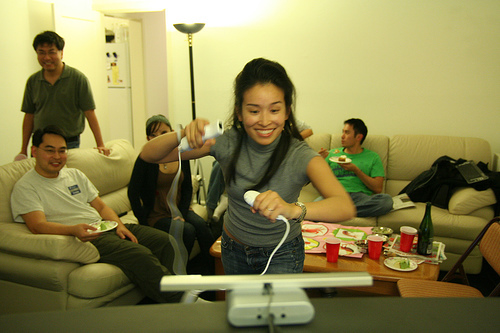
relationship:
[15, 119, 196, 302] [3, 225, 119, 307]
guy sitting on couch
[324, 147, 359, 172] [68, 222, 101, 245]
guy holding a plate in hand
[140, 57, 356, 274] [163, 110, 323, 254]
girl holding two controllers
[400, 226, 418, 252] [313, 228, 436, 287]
cup on table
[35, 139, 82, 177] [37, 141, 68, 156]
smiling man with glasses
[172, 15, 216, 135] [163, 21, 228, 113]
gold stand lamp by wall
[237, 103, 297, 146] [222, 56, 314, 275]
big smile on woman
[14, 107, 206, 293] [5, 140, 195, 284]
two people sitting on love seat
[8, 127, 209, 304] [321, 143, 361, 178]
guy wearing glasses holding plate of food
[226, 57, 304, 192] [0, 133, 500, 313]
dark long hair on couch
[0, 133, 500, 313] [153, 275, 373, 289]
couch playing wii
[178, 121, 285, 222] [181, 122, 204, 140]
two controllers in hand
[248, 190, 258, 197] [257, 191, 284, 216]
nunchuck in hand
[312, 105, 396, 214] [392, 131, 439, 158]
man eating on couch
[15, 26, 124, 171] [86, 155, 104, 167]
man standing behind couch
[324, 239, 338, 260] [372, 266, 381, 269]
cup on table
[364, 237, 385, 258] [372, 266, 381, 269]
cup on table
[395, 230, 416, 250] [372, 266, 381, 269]
cup on table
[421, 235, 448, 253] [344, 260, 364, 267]
corner of table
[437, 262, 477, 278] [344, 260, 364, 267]
chair by table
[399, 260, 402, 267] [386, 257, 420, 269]
food on utensil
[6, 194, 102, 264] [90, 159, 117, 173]
hand resting on couch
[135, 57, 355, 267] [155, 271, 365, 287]
girl playing wii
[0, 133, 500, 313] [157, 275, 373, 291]
couch playing video game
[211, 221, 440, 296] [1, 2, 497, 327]
coffee table in living room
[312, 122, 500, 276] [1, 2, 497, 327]
couch in living room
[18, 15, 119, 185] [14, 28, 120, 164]
man behind behind the couch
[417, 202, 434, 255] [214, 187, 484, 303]
bottle sitting on table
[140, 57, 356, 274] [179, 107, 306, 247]
girl holding wiimote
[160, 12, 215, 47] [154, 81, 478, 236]
light behind behind couch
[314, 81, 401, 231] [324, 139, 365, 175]
man holding plate